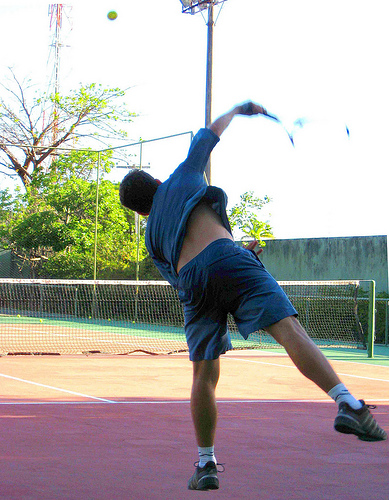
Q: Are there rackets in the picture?
A: Yes, there is a racket.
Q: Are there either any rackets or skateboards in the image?
A: Yes, there is a racket.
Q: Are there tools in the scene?
A: No, there are no tools.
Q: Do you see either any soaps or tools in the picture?
A: No, there are no tools or soaps.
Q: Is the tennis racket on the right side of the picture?
A: Yes, the tennis racket is on the right of the image.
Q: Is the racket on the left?
A: No, the racket is on the right of the image.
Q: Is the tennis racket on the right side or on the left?
A: The tennis racket is on the right of the image.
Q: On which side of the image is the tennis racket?
A: The tennis racket is on the right of the image.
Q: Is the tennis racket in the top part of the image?
A: Yes, the tennis racket is in the top of the image.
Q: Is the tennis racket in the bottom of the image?
A: No, the tennis racket is in the top of the image.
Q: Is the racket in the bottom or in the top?
A: The racket is in the top of the image.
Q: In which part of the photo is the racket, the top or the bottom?
A: The racket is in the top of the image.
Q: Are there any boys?
A: No, there are no boys.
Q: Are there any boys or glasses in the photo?
A: No, there are no boys or glasses.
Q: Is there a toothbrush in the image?
A: No, there are no toothbrushes.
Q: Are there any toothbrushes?
A: No, there are no toothbrushes.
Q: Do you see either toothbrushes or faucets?
A: No, there are no toothbrushes or faucets.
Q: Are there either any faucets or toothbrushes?
A: No, there are no toothbrushes or faucets.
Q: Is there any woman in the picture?
A: No, there are no women.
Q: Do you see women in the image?
A: No, there are no women.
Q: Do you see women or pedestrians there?
A: No, there are no women or pedestrians.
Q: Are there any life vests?
A: No, there are no life vests.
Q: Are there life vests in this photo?
A: No, there are no life vests.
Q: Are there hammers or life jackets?
A: No, there are no life jackets or hammers.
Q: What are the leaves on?
A: The leaves are on the tree.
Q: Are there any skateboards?
A: No, there are no skateboards.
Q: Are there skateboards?
A: No, there are no skateboards.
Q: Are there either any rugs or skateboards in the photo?
A: No, there are no skateboards or rugs.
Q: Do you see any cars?
A: No, there are no cars.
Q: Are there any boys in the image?
A: No, there are no boys.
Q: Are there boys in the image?
A: No, there are no boys.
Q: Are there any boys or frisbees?
A: No, there are no boys or frisbees.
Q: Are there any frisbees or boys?
A: No, there are no boys or frisbees.